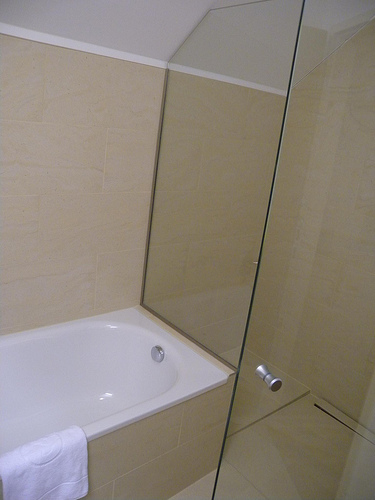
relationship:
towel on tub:
[42, 432, 87, 459] [73, 382, 139, 412]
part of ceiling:
[99, 23, 143, 35] [151, 13, 176, 36]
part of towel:
[99, 23, 143, 35] [42, 432, 87, 459]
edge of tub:
[200, 363, 240, 392] [73, 382, 139, 412]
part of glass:
[99, 23, 143, 35] [315, 42, 356, 53]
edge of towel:
[71, 418, 107, 447] [42, 432, 87, 459]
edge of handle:
[200, 363, 240, 392] [254, 358, 264, 392]